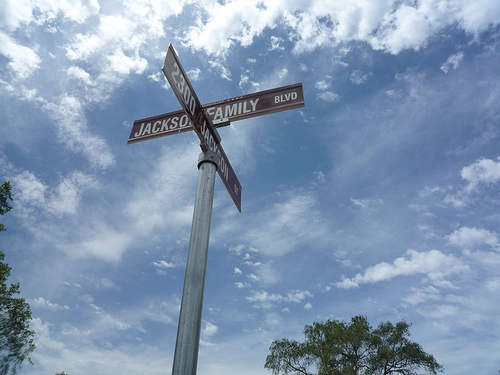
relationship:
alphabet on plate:
[126, 122, 144, 143] [129, 82, 307, 144]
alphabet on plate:
[140, 118, 158, 144] [129, 82, 307, 144]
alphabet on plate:
[148, 118, 162, 140] [123, 78, 306, 143]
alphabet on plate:
[238, 98, 248, 118] [126, 82, 308, 152]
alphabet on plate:
[158, 113, 169, 131] [129, 82, 307, 144]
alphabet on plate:
[220, 100, 242, 119] [123, 78, 306, 143]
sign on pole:
[126, 81, 305, 145] [150, 160, 240, 356]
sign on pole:
[126, 81, 305, 145] [138, 161, 251, 349]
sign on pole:
[165, 60, 325, 196] [127, 60, 221, 361]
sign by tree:
[136, 76, 326, 207] [260, 305, 432, 367]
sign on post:
[161, 42, 305, 213] [167, 161, 238, 335]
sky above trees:
[46, 49, 429, 281] [275, 297, 421, 359]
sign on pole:
[126, 81, 305, 145] [176, 185, 242, 356]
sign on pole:
[126, 81, 305, 145] [170, 160, 220, 375]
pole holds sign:
[107, 92, 257, 364] [154, 47, 281, 220]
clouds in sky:
[327, 182, 427, 301] [24, 6, 460, 343]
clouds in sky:
[328, 22, 448, 134] [0, 11, 474, 340]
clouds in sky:
[355, 20, 431, 77] [32, 26, 484, 353]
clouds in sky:
[360, 207, 473, 342] [18, 22, 433, 321]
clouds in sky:
[363, 20, 451, 83] [38, 33, 432, 341]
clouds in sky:
[343, 21, 413, 58] [32, 26, 484, 353]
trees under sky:
[5, 177, 433, 373] [4, 4, 484, 367]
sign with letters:
[161, 42, 305, 213] [207, 99, 255, 118]